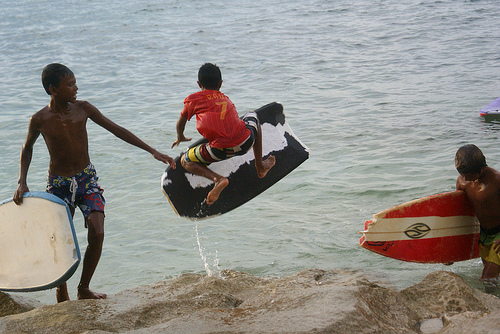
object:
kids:
[15, 62, 175, 301]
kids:
[171, 61, 275, 203]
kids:
[455, 144, 500, 277]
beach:
[2, 268, 498, 333]